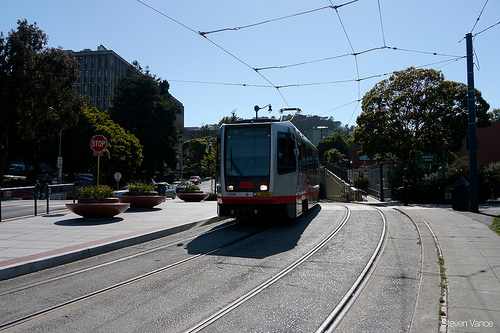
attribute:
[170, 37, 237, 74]
clouds — white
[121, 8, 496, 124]
sky — blue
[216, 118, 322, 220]
car — muni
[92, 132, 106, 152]
sign — red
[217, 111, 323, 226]
rail — light rail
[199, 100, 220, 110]
clouds — white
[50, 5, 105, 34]
sky — blue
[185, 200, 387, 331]
track — empty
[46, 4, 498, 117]
sky — blue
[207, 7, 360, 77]
wires — black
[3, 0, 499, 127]
sky — blue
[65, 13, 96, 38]
sky — blue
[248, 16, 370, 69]
sky — beautiful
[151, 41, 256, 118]
clouds — white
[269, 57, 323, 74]
train wire — black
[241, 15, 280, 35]
train wire — black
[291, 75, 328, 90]
train wire — black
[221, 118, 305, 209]
train — muni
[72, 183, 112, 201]
plant — outdoor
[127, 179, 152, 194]
plant — outdoor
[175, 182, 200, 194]
plant — outdoor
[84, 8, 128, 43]
clouds — white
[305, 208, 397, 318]
tracks — metal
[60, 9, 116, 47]
clouds — white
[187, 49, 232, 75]
clouds — white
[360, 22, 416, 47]
clouds — white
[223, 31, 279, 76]
sky — blue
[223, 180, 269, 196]
light — front light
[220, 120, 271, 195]
door — back door 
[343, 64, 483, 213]
tree — very big